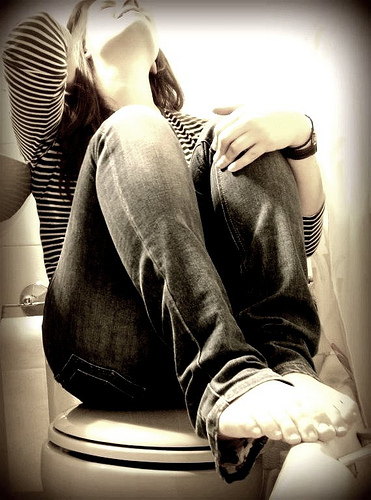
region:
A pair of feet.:
[221, 370, 369, 444]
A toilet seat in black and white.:
[38, 398, 221, 474]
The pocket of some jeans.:
[50, 351, 157, 416]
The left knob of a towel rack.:
[8, 282, 53, 315]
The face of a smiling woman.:
[58, 1, 181, 95]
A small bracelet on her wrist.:
[300, 112, 322, 159]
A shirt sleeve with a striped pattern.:
[10, 15, 61, 153]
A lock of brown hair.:
[151, 49, 186, 110]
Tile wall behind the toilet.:
[0, 364, 47, 423]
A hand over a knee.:
[205, 98, 320, 184]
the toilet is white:
[41, 334, 195, 487]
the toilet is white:
[86, 382, 212, 489]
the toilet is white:
[91, 406, 151, 487]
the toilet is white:
[5, 350, 277, 497]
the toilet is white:
[68, 366, 153, 484]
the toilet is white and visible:
[35, 339, 278, 488]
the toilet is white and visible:
[83, 388, 211, 492]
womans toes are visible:
[201, 407, 360, 467]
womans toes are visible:
[203, 377, 356, 450]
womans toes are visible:
[217, 402, 285, 448]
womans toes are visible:
[255, 412, 368, 485]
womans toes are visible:
[212, 420, 308, 464]